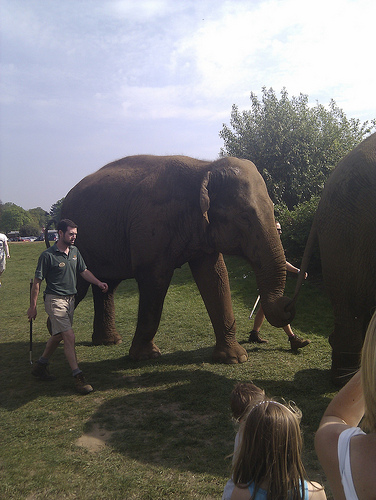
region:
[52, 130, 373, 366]
elephants on a lawn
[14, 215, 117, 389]
man next to elephants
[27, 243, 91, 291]
shirt on the man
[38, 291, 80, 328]
shorts on a man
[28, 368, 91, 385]
shoes on the man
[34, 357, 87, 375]
socks on the man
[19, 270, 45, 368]
pole in man's hands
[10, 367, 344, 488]
ground elephant walks on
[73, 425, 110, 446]
bare spot on ground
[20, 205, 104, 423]
the man is walking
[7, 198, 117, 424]
the man is walking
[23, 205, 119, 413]
the man is walking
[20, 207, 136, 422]
the man is walking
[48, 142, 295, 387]
the elephant is brown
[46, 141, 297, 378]
the elephant is brown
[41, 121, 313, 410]
the elephant is brown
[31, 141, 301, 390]
the elephant is brown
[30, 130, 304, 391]
the elephant is brown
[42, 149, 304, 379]
elephant walking on the grass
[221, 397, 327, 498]
back of a girl's head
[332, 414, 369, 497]
white strap around the shoulder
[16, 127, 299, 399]
man walking beside the elephant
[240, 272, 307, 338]
trunk attached to the tail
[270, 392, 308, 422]
strands of hair sticking up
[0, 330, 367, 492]
shadows on the ground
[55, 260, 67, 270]
name tag on the chest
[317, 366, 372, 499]
arm is lifted up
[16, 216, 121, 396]
a man that is a zookeeper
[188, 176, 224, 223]
the ear of an elephant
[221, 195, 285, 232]
the eyes of an elephant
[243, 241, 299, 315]
the trunk of an elephant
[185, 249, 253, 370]
the left leg of an elephant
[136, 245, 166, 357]
the right leg of an elephant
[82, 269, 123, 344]
the back leg of an elephant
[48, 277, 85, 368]
the legs of a man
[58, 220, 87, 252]
the head of a man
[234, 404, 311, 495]
A little girl with brown hair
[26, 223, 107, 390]
A man walking beside the elephant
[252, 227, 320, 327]
An elephant holding the tail of the one in front of it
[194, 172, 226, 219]
An elephant's ear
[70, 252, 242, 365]
The legs of an elephant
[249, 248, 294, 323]
An elephant's trunk curled around a tail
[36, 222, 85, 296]
A man in a green shirt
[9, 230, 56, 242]
Cars parked in the background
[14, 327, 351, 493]
The shadows of the elephants on the ground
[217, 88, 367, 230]
A tree behind the elephants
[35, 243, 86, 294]
shirt worn by human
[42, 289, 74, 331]
shorts worn by human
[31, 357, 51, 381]
boot worn by human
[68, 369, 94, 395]
boot worn by human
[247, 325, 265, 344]
boot worn by human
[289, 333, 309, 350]
boot worn by human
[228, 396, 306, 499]
hair is worn long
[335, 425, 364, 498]
garment worn by woman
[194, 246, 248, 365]
leg belongs to elephant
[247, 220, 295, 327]
trunk belongs to elephant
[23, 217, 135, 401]
man wearing green shirt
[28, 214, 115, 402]
man wearing khaki shorts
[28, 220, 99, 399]
man wearing brown shoes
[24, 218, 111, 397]
man standing near an elephant